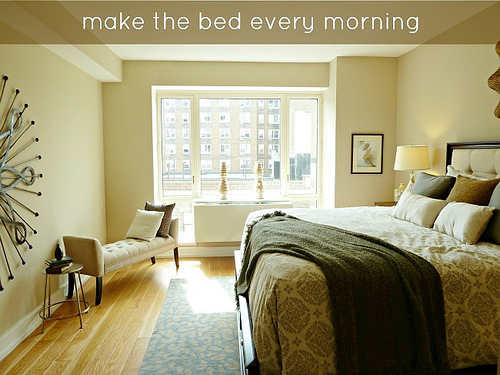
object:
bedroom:
[30, 32, 491, 343]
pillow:
[370, 162, 480, 255]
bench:
[168, 180, 318, 251]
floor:
[75, 289, 151, 373]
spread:
[202, 212, 411, 352]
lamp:
[357, 120, 440, 214]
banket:
[207, 213, 431, 352]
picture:
[330, 112, 427, 196]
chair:
[10, 249, 95, 372]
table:
[368, 188, 402, 209]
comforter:
[289, 205, 453, 320]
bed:
[231, 132, 492, 322]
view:
[145, 77, 333, 188]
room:
[50, 24, 471, 320]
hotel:
[52, 38, 456, 323]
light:
[388, 133, 432, 189]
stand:
[393, 202, 394, 203]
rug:
[142, 270, 237, 360]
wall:
[343, 116, 414, 198]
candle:
[382, 177, 409, 210]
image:
[352, 140, 382, 172]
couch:
[95, 238, 168, 272]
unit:
[192, 195, 242, 247]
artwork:
[342, 133, 381, 172]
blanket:
[221, 188, 329, 254]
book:
[43, 246, 99, 277]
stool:
[27, 244, 123, 335]